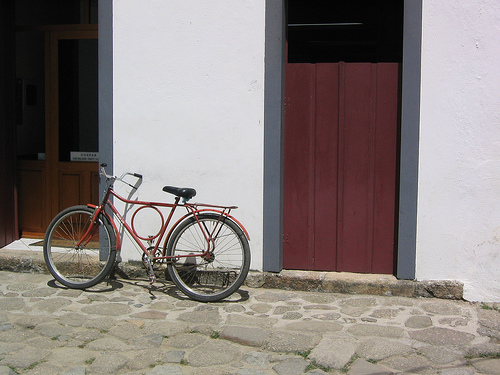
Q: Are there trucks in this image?
A: No, there are no trucks.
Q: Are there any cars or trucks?
A: No, there are no trucks or cars.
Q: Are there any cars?
A: No, there are no cars.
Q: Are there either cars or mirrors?
A: No, there are no cars or mirrors.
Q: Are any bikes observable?
A: Yes, there is a bike.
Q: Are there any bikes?
A: Yes, there is a bike.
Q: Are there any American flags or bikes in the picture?
A: Yes, there is a bike.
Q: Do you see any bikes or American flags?
A: Yes, there is a bike.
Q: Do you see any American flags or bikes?
A: Yes, there is a bike.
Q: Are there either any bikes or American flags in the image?
A: Yes, there is a bike.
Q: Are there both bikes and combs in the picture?
A: No, there is a bike but no combs.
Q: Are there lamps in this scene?
A: No, there are no lamps.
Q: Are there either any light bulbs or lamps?
A: No, there are no lamps or light bulbs.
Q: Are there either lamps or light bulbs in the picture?
A: No, there are no lamps or light bulbs.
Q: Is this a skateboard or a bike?
A: This is a bike.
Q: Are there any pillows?
A: No, there are no pillows.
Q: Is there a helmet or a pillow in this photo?
A: No, there are no pillows or helmets.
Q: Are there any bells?
A: No, there are no bells.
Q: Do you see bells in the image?
A: No, there are no bells.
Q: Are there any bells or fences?
A: No, there are no bells or fences.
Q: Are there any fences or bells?
A: No, there are no bells or fences.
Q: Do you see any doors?
A: Yes, there is a door.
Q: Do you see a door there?
A: Yes, there is a door.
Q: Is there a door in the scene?
A: Yes, there is a door.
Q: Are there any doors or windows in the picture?
A: Yes, there is a door.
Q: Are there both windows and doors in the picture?
A: No, there is a door but no windows.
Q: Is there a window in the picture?
A: No, there are no windows.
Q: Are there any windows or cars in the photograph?
A: No, there are no windows or cars.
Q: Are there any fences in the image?
A: No, there are no fences.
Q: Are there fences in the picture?
A: No, there are no fences.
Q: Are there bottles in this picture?
A: No, there are no bottles.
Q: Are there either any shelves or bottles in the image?
A: No, there are no bottles or shelves.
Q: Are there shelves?
A: No, there are no shelves.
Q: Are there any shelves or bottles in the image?
A: No, there are no shelves or bottles.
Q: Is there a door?
A: Yes, there is a door.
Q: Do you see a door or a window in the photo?
A: Yes, there is a door.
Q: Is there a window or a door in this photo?
A: Yes, there is a door.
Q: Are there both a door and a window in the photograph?
A: No, there is a door but no windows.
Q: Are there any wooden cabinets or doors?
A: Yes, there is a wood door.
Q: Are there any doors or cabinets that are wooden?
A: Yes, the door is wooden.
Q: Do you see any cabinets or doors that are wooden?
A: Yes, the door is wooden.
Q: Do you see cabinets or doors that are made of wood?
A: Yes, the door is made of wood.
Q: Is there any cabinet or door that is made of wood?
A: Yes, the door is made of wood.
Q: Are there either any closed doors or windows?
A: Yes, there is a closed door.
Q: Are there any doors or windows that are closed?
A: Yes, the door is closed.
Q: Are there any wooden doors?
A: Yes, there is a wood door.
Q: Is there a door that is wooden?
A: Yes, there is a door that is wooden.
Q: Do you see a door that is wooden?
A: Yes, there is a door that is wooden.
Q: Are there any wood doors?
A: Yes, there is a door that is made of wood.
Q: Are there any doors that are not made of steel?
A: Yes, there is a door that is made of wood.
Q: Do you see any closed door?
A: Yes, there is a closed door.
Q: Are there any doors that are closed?
A: Yes, there is a door that is closed.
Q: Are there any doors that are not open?
A: Yes, there is an closed door.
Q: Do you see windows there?
A: No, there are no windows.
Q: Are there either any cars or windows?
A: No, there are no windows or cars.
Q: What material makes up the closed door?
A: The door is made of wood.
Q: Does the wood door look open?
A: No, the door is closed.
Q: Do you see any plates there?
A: Yes, there is a plate.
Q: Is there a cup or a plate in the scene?
A: Yes, there is a plate.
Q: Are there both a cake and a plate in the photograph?
A: No, there is a plate but no cakes.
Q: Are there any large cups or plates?
A: Yes, there is a large plate.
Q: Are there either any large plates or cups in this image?
A: Yes, there is a large plate.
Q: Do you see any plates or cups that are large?
A: Yes, the plate is large.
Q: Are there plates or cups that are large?
A: Yes, the plate is large.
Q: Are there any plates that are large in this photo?
A: Yes, there is a large plate.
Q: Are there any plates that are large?
A: Yes, there is a plate that is large.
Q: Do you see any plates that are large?
A: Yes, there is a plate that is large.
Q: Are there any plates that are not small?
A: Yes, there is a large plate.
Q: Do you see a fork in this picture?
A: No, there are no forks.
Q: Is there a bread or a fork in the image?
A: No, there are no forks or breads.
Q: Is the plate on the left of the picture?
A: Yes, the plate is on the left of the image.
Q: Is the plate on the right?
A: No, the plate is on the left of the image.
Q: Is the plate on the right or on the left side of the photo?
A: The plate is on the left of the image.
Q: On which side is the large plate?
A: The plate is on the left of the image.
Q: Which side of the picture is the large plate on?
A: The plate is on the left of the image.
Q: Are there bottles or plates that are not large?
A: No, there is a plate but it is large.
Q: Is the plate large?
A: Yes, the plate is large.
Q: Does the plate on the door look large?
A: Yes, the plate is large.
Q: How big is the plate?
A: The plate is large.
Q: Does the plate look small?
A: No, the plate is large.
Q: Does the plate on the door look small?
A: No, the plate is large.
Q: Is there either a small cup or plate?
A: No, there is a plate but it is large.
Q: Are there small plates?
A: No, there is a plate but it is large.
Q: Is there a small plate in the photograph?
A: No, there is a plate but it is large.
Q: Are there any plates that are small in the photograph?
A: No, there is a plate but it is large.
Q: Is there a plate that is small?
A: No, there is a plate but it is large.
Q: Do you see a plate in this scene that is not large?
A: No, there is a plate but it is large.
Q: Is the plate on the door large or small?
A: The plate is large.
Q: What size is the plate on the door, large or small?
A: The plate is large.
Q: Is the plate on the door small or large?
A: The plate is large.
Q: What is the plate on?
A: The plate is on the door.